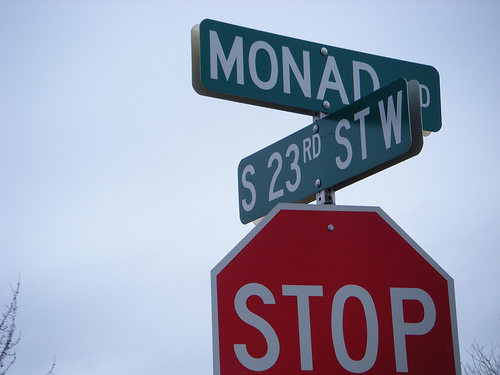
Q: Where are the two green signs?
A: Above the stop sign.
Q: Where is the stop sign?
A: On the pole.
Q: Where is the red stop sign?
A: Under the green signs.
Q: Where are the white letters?
A: On the stop sign.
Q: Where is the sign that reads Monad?
A: On top.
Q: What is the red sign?
A: Stop sign.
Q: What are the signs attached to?
A: Metal post.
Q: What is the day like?
A: Overcast.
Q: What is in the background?
A: Tree limbs.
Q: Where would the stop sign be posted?
A: End of the street.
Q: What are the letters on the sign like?
A: Capital.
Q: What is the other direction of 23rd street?
A: South.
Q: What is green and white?
A: A sign.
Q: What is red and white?
A: A stop sign.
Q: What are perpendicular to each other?
A: The signs.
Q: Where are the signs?
A: On top of each other.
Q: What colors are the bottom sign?
A: Red and White.